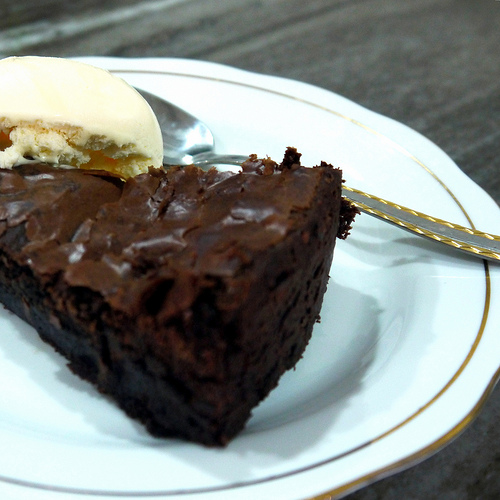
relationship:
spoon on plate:
[135, 85, 495, 269] [3, 47, 474, 499]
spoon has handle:
[135, 85, 495, 269] [160, 128, 500, 263]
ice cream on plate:
[5, 54, 174, 167] [3, 47, 474, 499]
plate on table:
[3, 47, 474, 499] [30, 6, 498, 165]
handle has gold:
[160, 128, 500, 263] [343, 186, 496, 256]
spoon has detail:
[135, 85, 495, 269] [356, 186, 499, 252]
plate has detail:
[3, 47, 474, 499] [132, 65, 296, 105]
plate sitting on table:
[3, 47, 474, 499] [30, 6, 498, 165]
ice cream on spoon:
[5, 54, 174, 167] [135, 85, 495, 269]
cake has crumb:
[3, 159, 354, 411] [336, 204, 368, 240]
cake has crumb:
[3, 159, 354, 411] [270, 148, 314, 168]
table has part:
[30, 6, 498, 165] [309, 9, 486, 94]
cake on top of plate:
[3, 159, 354, 411] [3, 47, 474, 499]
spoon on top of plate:
[135, 85, 495, 269] [3, 47, 474, 499]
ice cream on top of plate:
[5, 54, 174, 167] [3, 47, 474, 499]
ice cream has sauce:
[5, 54, 174, 167] [25, 120, 135, 168]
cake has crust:
[3, 159, 354, 411] [39, 173, 274, 256]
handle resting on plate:
[232, 124, 499, 265] [3, 47, 474, 499]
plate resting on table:
[3, 47, 474, 499] [30, 6, 498, 165]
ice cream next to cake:
[5, 54, 174, 167] [3, 159, 354, 411]